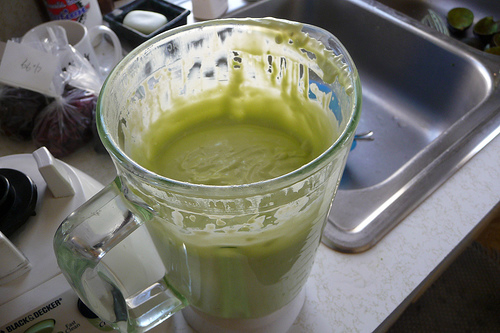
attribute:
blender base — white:
[1, 146, 142, 331]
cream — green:
[176, 122, 271, 174]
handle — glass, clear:
[50, 175, 185, 331]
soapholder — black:
[120, 4, 192, 38]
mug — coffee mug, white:
[16, 15, 127, 85]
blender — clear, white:
[68, 36, 360, 331]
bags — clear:
[2, 26, 99, 145]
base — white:
[4, 145, 191, 324]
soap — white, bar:
[120, 6, 177, 41]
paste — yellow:
[205, 117, 249, 156]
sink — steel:
[209, 2, 497, 193]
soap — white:
[120, 9, 170, 37]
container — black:
[106, 5, 202, 51]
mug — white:
[11, 4, 68, 56]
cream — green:
[151, 114, 382, 244]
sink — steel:
[220, 0, 499, 254]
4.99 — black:
[19, 58, 42, 74]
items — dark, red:
[34, 104, 90, 158]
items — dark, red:
[2, 86, 49, 144]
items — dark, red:
[67, 86, 97, 145]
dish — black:
[100, 0, 194, 49]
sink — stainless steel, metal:
[172, 0, 484, 263]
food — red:
[4, 85, 97, 157]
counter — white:
[1, 137, 498, 331]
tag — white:
[1, 38, 61, 98]